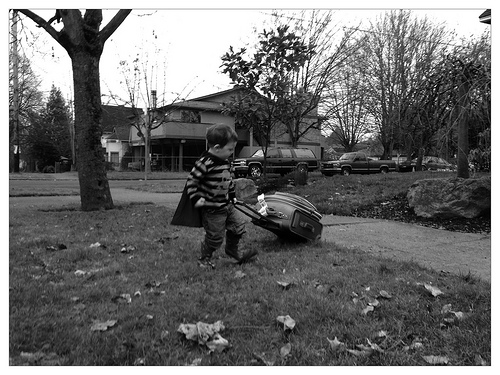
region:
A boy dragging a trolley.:
[183, 151, 318, 341]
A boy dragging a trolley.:
[181, 113, 279, 251]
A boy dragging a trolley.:
[228, 155, 293, 268]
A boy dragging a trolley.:
[158, 74, 311, 291]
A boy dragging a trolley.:
[213, 123, 315, 288]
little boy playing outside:
[178, 117, 260, 270]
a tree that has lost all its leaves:
[9, 8, 160, 215]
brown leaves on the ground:
[177, 320, 240, 355]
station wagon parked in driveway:
[233, 142, 327, 182]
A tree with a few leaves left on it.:
[100, 43, 225, 190]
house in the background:
[116, 78, 328, 172]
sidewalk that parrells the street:
[348, 215, 490, 286]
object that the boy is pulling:
[231, 189, 332, 246]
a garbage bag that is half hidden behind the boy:
[171, 165, 208, 227]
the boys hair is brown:
[204, 125, 241, 163]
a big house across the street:
[106, 83, 321, 159]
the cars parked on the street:
[233, 132, 450, 174]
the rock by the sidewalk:
[410, 173, 482, 225]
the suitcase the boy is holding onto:
[228, 186, 319, 238]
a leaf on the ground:
[174, 317, 231, 352]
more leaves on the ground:
[272, 266, 472, 368]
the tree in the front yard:
[24, 11, 131, 206]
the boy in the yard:
[172, 123, 252, 261]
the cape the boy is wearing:
[170, 152, 230, 232]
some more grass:
[288, 165, 444, 226]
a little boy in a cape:
[166, 124, 264, 263]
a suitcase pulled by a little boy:
[231, 180, 335, 242]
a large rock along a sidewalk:
[404, 171, 490, 221]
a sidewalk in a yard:
[111, 186, 488, 282]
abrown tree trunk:
[18, 10, 136, 210]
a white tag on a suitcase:
[250, 188, 278, 219]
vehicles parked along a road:
[229, 139, 455, 178]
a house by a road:
[124, 77, 327, 174]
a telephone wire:
[266, 11, 488, 44]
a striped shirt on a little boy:
[186, 151, 242, 217]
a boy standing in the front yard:
[183, 125, 243, 257]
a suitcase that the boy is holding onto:
[236, 190, 323, 242]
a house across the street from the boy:
[101, 86, 327, 172]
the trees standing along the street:
[223, 13, 493, 168]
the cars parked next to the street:
[233, 145, 458, 177]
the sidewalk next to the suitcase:
[114, 182, 493, 303]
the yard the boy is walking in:
[16, 210, 490, 359]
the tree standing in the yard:
[20, 10, 130, 209]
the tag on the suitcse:
[252, 193, 272, 222]